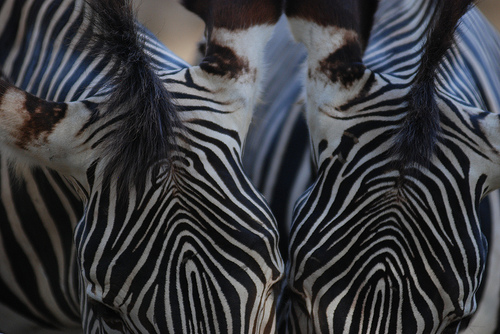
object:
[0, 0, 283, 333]
zebra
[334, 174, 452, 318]
stripes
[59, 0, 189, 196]
hair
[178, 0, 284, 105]
ears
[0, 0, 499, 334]
picture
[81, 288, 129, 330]
eyes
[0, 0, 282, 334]
head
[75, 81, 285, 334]
face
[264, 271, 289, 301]
eye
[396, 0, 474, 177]
mane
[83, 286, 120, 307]
eyelid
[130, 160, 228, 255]
forehead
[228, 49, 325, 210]
stomach